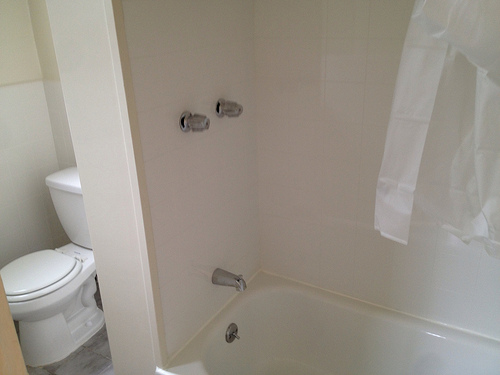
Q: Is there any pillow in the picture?
A: No, there are no pillows.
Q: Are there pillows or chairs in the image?
A: No, there are no pillows or chairs.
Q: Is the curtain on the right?
A: Yes, the curtain is on the right of the image.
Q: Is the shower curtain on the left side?
A: No, the curtain is on the right of the image.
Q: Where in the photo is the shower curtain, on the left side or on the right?
A: The curtain is on the right of the image.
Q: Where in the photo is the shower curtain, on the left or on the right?
A: The curtain is on the right of the image.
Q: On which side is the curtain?
A: The curtain is on the right of the image.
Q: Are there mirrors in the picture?
A: No, there are no mirrors.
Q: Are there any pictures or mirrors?
A: No, there are no mirrors or pictures.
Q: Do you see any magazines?
A: No, there are no magazines.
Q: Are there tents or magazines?
A: No, there are no magazines or tents.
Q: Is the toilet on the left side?
A: Yes, the toilet is on the left of the image.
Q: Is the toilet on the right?
A: No, the toilet is on the left of the image.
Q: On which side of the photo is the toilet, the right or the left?
A: The toilet is on the left of the image.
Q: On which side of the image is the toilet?
A: The toilet is on the left of the image.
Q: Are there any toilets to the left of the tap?
A: Yes, there is a toilet to the left of the tap.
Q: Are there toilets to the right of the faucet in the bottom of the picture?
A: No, the toilet is to the left of the faucet.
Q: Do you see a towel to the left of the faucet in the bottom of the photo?
A: No, there is a toilet to the left of the faucet.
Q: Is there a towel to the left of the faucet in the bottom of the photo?
A: No, there is a toilet to the left of the faucet.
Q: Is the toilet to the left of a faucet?
A: Yes, the toilet is to the left of a faucet.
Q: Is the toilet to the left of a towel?
A: No, the toilet is to the left of a faucet.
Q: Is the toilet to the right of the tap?
A: No, the toilet is to the left of the tap.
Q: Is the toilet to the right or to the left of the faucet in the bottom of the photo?
A: The toilet is to the left of the tap.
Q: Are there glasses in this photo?
A: No, there are no glasses.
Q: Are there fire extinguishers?
A: No, there are no fire extinguishers.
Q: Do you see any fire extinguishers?
A: No, there are no fire extinguishers.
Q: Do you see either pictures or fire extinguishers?
A: No, there are no fire extinguishers or pictures.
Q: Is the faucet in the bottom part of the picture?
A: Yes, the faucet is in the bottom of the image.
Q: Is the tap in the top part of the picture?
A: No, the tap is in the bottom of the image.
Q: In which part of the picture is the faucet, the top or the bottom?
A: The faucet is in the bottom of the image.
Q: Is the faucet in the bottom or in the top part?
A: The faucet is in the bottom of the image.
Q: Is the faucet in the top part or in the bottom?
A: The faucet is in the bottom of the image.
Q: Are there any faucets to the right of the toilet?
A: Yes, there is a faucet to the right of the toilet.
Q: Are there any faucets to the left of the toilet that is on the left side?
A: No, the faucet is to the right of the toilet.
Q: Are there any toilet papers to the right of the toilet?
A: No, there is a faucet to the right of the toilet.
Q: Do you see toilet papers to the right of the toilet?
A: No, there is a faucet to the right of the toilet.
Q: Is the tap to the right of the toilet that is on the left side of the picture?
A: Yes, the tap is to the right of the toilet.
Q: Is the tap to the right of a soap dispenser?
A: No, the tap is to the right of the toilet.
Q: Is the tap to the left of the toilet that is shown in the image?
A: No, the tap is to the right of the toilet.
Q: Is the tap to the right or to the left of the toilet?
A: The tap is to the right of the toilet.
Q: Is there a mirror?
A: No, there are no mirrors.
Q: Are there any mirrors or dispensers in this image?
A: No, there are no mirrors or dispensers.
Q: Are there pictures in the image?
A: No, there are no pictures.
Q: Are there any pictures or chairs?
A: No, there are no pictures or chairs.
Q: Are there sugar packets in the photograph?
A: No, there are no sugar packets.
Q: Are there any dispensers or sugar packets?
A: No, there are no sugar packets or dispensers.